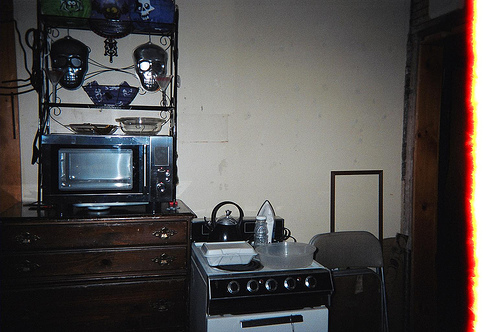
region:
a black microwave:
[35, 134, 176, 209]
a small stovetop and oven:
[188, 216, 333, 328]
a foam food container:
[197, 240, 256, 265]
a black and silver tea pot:
[200, 199, 247, 243]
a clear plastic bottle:
[252, 216, 267, 243]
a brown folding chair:
[308, 228, 385, 328]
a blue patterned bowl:
[74, 81, 139, 108]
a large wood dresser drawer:
[0, 199, 191, 326]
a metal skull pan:
[130, 42, 165, 91]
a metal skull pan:
[51, 34, 85, 87]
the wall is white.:
[178, 2, 377, 217]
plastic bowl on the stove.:
[259, 236, 324, 266]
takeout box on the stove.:
[194, 235, 256, 270]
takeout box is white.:
[192, 231, 253, 268]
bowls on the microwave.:
[69, 110, 166, 138]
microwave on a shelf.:
[27, 124, 178, 211]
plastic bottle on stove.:
[247, 207, 268, 247]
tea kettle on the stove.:
[205, 196, 255, 234]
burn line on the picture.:
[446, 2, 483, 329]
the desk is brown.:
[9, 189, 194, 320]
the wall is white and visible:
[235, 43, 396, 248]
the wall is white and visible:
[182, 42, 353, 200]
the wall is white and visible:
[226, 116, 291, 167]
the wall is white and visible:
[215, 110, 340, 327]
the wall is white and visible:
[235, 115, 320, 240]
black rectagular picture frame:
[294, 138, 416, 227]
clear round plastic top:
[270, 232, 317, 264]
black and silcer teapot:
[201, 207, 255, 240]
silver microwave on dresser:
[24, 117, 209, 230]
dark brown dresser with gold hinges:
[35, 198, 151, 309]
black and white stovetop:
[198, 265, 341, 330]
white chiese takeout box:
[201, 235, 268, 286]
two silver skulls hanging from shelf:
[64, 17, 231, 123]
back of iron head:
[250, 210, 286, 247]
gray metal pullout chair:
[303, 228, 392, 286]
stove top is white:
[192, 201, 323, 273]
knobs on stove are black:
[218, 274, 327, 301]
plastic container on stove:
[255, 236, 315, 278]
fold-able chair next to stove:
[309, 210, 424, 327]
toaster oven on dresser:
[35, 127, 184, 227]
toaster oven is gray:
[30, 122, 202, 239]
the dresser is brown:
[13, 208, 187, 328]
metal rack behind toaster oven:
[33, 0, 195, 148]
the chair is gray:
[313, 219, 428, 329]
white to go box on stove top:
[200, 234, 264, 279]